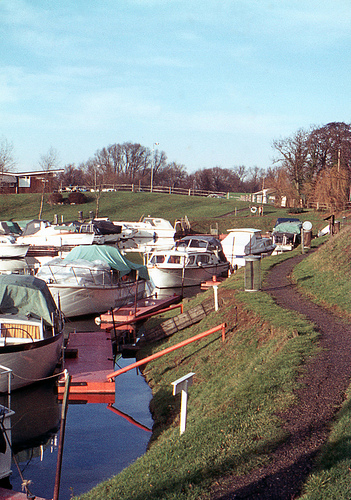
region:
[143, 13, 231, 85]
sky above the ground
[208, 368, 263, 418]
grass on the ground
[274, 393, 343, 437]
black street on the ground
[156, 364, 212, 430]
white sign on ground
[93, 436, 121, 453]
water next to grass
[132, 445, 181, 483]
grass hill next to water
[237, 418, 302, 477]
shadow on the ground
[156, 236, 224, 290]
white boat in water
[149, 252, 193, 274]
windows on the boat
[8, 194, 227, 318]
many different boats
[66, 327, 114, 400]
dock next to boat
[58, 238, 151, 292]
green cover on the boat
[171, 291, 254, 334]
wooden board steps to the dock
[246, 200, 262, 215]
life jacket on the pole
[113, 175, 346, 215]
fence along the hill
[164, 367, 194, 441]
white sign in the grass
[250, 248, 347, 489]
pathway along the water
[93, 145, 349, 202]
trees behind the fence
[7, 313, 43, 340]
yellow curtains on the boat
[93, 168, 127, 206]
tree does not have leaves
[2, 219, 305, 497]
a small body of water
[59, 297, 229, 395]
a red metal dock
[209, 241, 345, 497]
a curing dirt path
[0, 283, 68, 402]
a small white boat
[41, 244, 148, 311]
a small white boat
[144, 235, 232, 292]
a small white boat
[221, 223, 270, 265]
a small white boat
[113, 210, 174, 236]
a small white boat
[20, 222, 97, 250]
a small white boat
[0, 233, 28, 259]
a small white boat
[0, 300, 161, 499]
THE WATER IS CALM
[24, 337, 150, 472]
THE WATER IS REFLECTING THE DOCK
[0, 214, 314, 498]
MANY BOATS TOGETHER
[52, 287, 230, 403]
THE DOCK IS RED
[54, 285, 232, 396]
TWO DOCKS SIDE BY SIDE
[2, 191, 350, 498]
THE GRASS IS PATCHY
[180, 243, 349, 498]
THE TRAIL IS BLACK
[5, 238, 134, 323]
SOME BOATS HAVE COVERS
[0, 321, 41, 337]
THE CURTAIN IS YELLOW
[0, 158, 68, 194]
THE BUILDING IS BROWN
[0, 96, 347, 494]
a harbor with lots of white boats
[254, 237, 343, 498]
curvy path next to the harbor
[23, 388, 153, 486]
reflective blue water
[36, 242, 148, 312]
white motor boat with green covering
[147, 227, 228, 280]
white motor boat with blue covering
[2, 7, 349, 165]
blue sky with some faint white clouds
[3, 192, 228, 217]
green grass on the hillside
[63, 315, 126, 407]
a red boat dock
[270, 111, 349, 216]
brown trees with no leaves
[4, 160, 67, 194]
a little brown shack